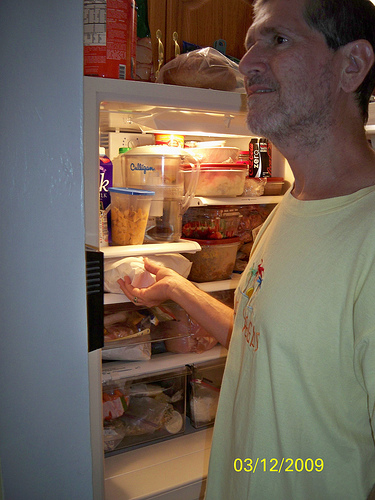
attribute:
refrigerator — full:
[0, 120, 375, 498]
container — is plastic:
[106, 184, 154, 245]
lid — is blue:
[108, 185, 154, 197]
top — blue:
[117, 175, 156, 205]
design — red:
[230, 253, 270, 351]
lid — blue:
[184, 233, 257, 245]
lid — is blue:
[104, 172, 167, 243]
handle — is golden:
[155, 27, 163, 81]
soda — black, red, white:
[248, 138, 267, 180]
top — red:
[194, 234, 243, 247]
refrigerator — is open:
[81, 77, 297, 498]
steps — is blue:
[99, 144, 115, 242]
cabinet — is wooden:
[85, 3, 265, 93]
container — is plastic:
[183, 231, 244, 281]